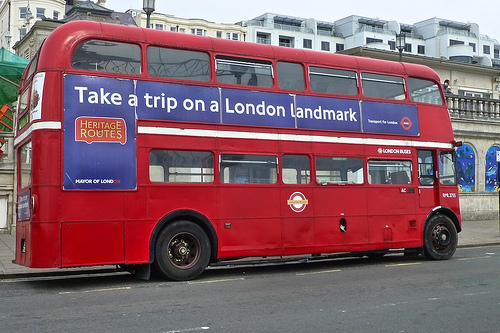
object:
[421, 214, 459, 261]
front tire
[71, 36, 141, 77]
windows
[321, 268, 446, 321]
gray pavement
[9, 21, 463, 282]
bus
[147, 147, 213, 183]
passenger window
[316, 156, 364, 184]
passenger window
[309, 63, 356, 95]
passenger window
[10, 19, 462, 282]
double-decker bus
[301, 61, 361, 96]
rock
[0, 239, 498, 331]
street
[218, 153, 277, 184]
window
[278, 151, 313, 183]
window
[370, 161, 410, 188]
window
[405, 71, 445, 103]
window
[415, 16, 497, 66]
building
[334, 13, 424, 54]
building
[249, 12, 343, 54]
building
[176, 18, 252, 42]
building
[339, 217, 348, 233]
gas input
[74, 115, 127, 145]
logo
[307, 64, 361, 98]
window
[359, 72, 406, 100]
window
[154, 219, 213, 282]
back wheel